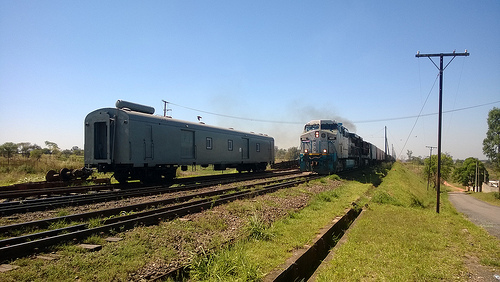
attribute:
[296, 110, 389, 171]
train — silver, blue, white, grey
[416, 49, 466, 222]
utility pole — wooden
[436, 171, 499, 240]
road — paved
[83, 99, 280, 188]
train car — silver, unattached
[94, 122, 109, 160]
door — open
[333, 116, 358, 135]
smoke — grey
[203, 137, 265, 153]
windows — small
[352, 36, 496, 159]
power line — electrical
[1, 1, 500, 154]
sky — blue, clear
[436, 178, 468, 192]
trail — clay colored